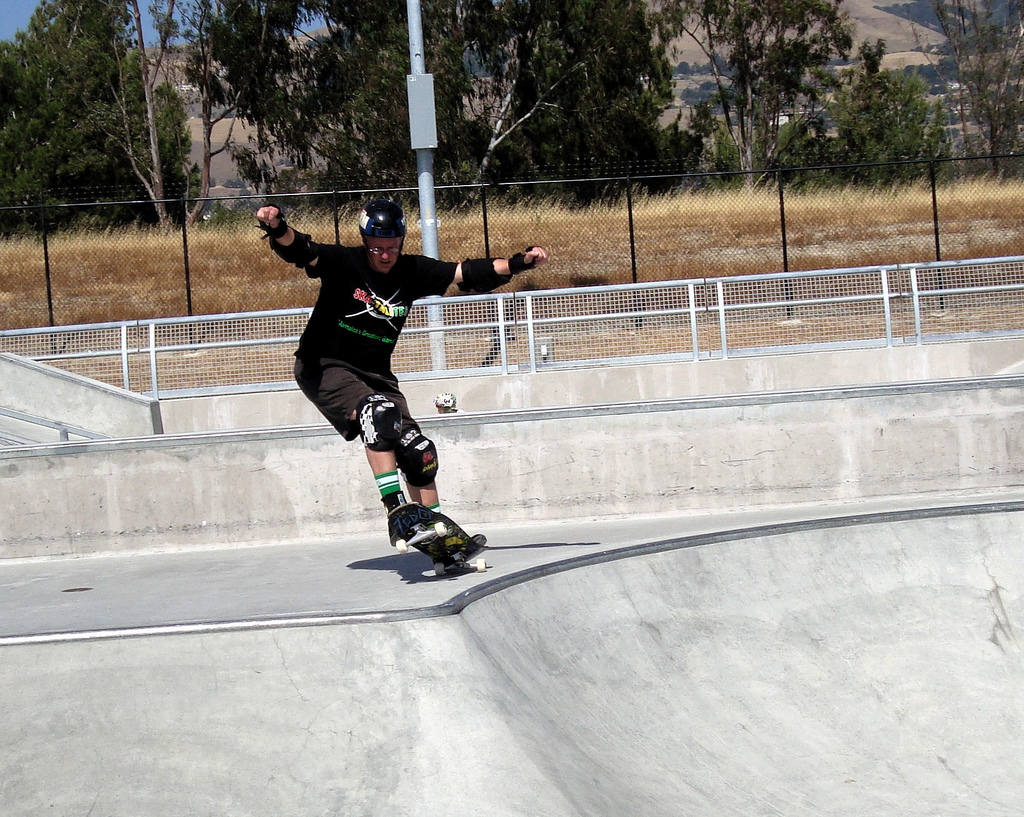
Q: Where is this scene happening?
A: Skate park.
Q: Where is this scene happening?
A: Skatepark.